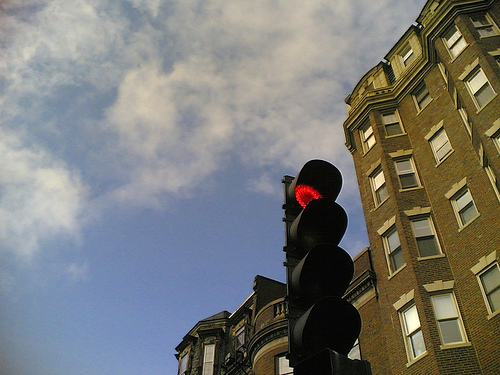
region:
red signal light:
[264, 145, 365, 346]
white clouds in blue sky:
[11, 21, 63, 71]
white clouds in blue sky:
[157, 65, 199, 115]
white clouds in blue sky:
[75, 188, 122, 230]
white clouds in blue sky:
[144, 56, 201, 103]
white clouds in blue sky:
[124, 129, 168, 176]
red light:
[282, 151, 330, 206]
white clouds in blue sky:
[154, 55, 205, 136]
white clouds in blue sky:
[40, 115, 78, 175]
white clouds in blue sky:
[130, 223, 155, 254]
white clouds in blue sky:
[41, 229, 106, 279]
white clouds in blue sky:
[198, 115, 263, 180]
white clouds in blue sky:
[2, 153, 107, 273]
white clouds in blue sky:
[64, 86, 125, 157]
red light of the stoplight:
[286, 174, 328, 206]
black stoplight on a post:
[274, 168, 363, 374]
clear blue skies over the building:
[116, 241, 203, 321]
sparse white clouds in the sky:
[28, 34, 207, 209]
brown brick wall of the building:
[451, 236, 473, 276]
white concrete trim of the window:
[441, 183, 481, 232]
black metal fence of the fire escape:
[216, 338, 250, 372]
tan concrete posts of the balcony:
[272, 301, 290, 318]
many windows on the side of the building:
[356, 66, 494, 351]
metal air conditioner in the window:
[218, 349, 238, 366]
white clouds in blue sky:
[2, 26, 64, 83]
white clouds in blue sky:
[72, 136, 132, 188]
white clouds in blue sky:
[110, 153, 171, 214]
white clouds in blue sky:
[34, 186, 108, 250]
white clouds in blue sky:
[177, 23, 258, 80]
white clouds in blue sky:
[100, 81, 168, 141]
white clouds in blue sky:
[90, 89, 192, 177]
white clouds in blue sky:
[242, 16, 293, 58]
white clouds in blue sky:
[57, 25, 115, 80]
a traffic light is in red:
[275, 150, 367, 372]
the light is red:
[286, 165, 331, 210]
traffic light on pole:
[272, 158, 371, 372]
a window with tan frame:
[361, 159, 396, 214]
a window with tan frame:
[424, 275, 473, 355]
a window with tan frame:
[437, 174, 487, 239]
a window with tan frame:
[420, 118, 458, 170]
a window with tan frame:
[453, 55, 499, 111]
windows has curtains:
[395, 274, 472, 371]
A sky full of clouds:
[0, 0, 425, 373]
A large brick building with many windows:
[173, 13, 494, 373]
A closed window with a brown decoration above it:
[405, 206, 447, 267]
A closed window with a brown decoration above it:
[440, 174, 480, 230]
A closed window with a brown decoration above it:
[422, 275, 476, 351]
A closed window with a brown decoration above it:
[388, 286, 435, 368]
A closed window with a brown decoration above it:
[359, 158, 395, 210]